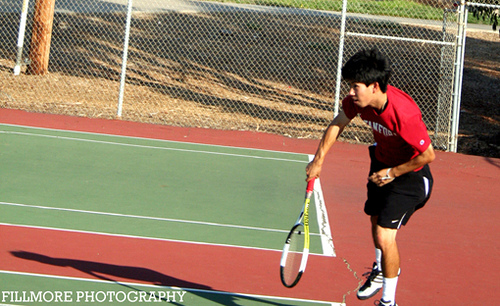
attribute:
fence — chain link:
[1, 0, 468, 151]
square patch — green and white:
[0, 122, 338, 257]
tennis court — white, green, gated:
[0, 107, 496, 304]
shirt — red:
[337, 86, 438, 171]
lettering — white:
[0, 284, 188, 304]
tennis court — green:
[3, 121, 347, 304]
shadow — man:
[14, 243, 273, 304]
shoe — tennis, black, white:
[376, 295, 397, 304]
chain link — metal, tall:
[118, 50, 221, 111]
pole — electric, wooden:
[26, 0, 56, 75]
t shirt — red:
[342, 86, 432, 170]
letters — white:
[361, 115, 393, 141]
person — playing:
[305, 48, 449, 304]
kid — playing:
[279, 46, 432, 304]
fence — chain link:
[154, 18, 314, 101]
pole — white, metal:
[12, 0, 31, 77]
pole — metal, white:
[113, 0, 133, 117]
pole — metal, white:
[333, 0, 347, 117]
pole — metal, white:
[448, 0, 465, 152]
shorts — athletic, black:
[363, 147, 436, 227]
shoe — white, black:
[349, 260, 390, 300]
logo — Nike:
[386, 215, 402, 228]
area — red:
[8, 117, 484, 273]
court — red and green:
[12, 100, 499, 294]